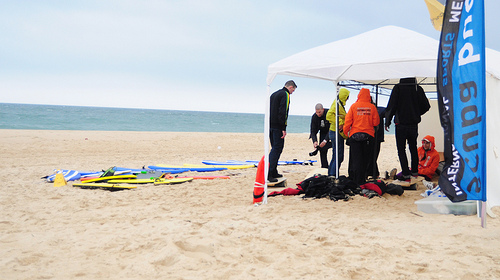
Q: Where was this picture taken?
A: Beach.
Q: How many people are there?
A: 7.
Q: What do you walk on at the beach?
A: Sand.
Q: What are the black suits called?
A: Wetsuits.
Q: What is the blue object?
A: A sign.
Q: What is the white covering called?
A: A tent.